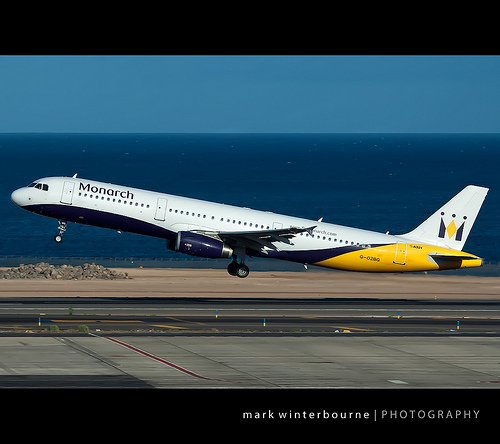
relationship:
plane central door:
[11, 171, 489, 276] [155, 195, 171, 224]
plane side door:
[11, 171, 489, 276] [155, 195, 171, 224]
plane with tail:
[11, 171, 489, 276] [398, 185, 492, 270]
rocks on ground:
[1, 262, 134, 281] [1, 262, 498, 390]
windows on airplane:
[79, 190, 370, 250] [11, 171, 489, 276]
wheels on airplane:
[54, 233, 250, 277] [11, 171, 489, 276]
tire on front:
[54, 233, 64, 243] [10, 166, 76, 244]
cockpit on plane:
[41, 183, 49, 192] [11, 171, 489, 276]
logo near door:
[79, 182, 135, 199] [155, 195, 171, 224]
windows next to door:
[78, 191, 82, 195] [60, 182, 75, 207]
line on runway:
[101, 334, 210, 381] [1, 334, 470, 389]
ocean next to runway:
[1, 133, 500, 262] [1, 334, 470, 389]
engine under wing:
[170, 231, 233, 257] [192, 218, 323, 248]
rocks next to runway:
[1, 262, 134, 281] [1, 334, 470, 389]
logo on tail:
[438, 211, 466, 242] [398, 185, 492, 270]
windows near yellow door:
[78, 191, 82, 195] [395, 242, 407, 265]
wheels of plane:
[54, 233, 64, 243] [11, 171, 489, 276]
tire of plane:
[54, 233, 64, 243] [11, 171, 489, 276]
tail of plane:
[398, 185, 492, 270] [11, 171, 489, 276]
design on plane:
[310, 184, 490, 272] [11, 171, 489, 276]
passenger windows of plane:
[79, 190, 370, 250] [11, 171, 489, 276]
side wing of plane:
[192, 218, 323, 248] [11, 171, 489, 276]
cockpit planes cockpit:
[12, 176, 66, 224] [41, 183, 49, 192]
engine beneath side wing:
[170, 231, 233, 257] [192, 218, 323, 248]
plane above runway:
[11, 171, 489, 276] [1, 334, 470, 389]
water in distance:
[1, 133, 500, 262] [1, 54, 500, 386]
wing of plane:
[192, 218, 323, 248] [11, 171, 489, 276]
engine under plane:
[170, 231, 233, 257] [11, 171, 489, 276]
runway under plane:
[1, 334, 470, 389] [11, 171, 489, 276]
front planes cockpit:
[10, 166, 76, 244] [12, 176, 66, 224]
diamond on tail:
[446, 218, 458, 239] [398, 185, 492, 270]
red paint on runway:
[101, 334, 210, 381] [1, 334, 470, 389]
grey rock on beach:
[1, 262, 134, 281] [1, 259, 500, 303]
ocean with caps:
[1, 133, 500, 262] [77, 133, 499, 179]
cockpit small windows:
[12, 176, 66, 224] [79, 190, 370, 250]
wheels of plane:
[235, 264, 251, 278] [6, 156, 483, 286]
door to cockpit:
[57, 179, 80, 209] [41, 183, 49, 192]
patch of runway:
[1, 334, 470, 389] [1, 334, 470, 389]